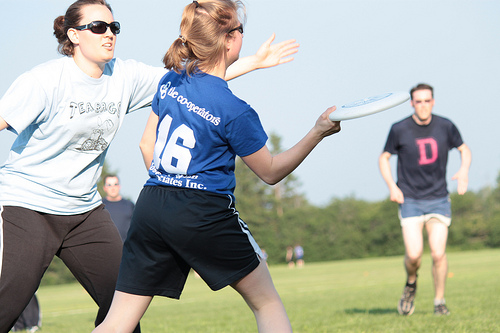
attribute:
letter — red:
[410, 134, 445, 165]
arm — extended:
[119, 28, 310, 93]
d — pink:
[415, 136, 438, 167]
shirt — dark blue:
[387, 112, 462, 199]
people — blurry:
[294, 242, 306, 267]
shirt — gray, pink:
[382, 111, 464, 196]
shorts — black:
[102, 179, 279, 306]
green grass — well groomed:
[0, 250, 499, 330]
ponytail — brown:
[53, 15, 73, 56]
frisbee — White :
[328, 90, 410, 122]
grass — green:
[65, 255, 497, 330]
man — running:
[365, 82, 466, 332]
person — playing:
[166, 2, 275, 132]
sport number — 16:
[149, 108, 204, 184]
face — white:
[405, 79, 440, 126]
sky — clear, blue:
[243, 2, 498, 121]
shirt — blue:
[141, 73, 269, 190]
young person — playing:
[380, 82, 472, 321]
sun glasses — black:
[72, 22, 123, 32]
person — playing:
[2, 4, 304, 331]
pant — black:
[0, 184, 167, 331]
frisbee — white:
[329, 87, 411, 122]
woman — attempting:
[1, 2, 192, 332]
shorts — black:
[111, 182, 270, 298]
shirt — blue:
[118, 51, 255, 205]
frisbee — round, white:
[331, 93, 409, 120]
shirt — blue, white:
[142, 60, 272, 195]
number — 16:
[146, 111, 202, 176]